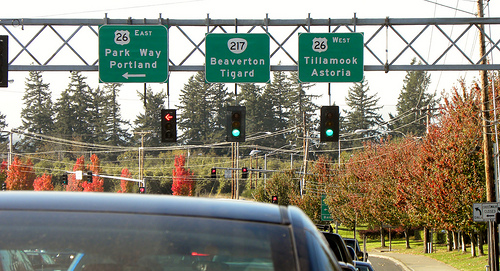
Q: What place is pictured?
A: It is a street.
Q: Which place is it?
A: It is a street.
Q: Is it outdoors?
A: Yes, it is outdoors.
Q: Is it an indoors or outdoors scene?
A: It is outdoors.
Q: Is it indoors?
A: No, it is outdoors.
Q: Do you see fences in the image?
A: No, there are no fences.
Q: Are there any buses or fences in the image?
A: No, there are no fences or buses.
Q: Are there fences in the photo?
A: No, there are no fences.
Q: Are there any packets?
A: No, there are no packets.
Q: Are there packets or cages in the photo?
A: No, there are no packets or cages.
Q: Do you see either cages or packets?
A: No, there are no packets or cages.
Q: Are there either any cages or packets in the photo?
A: No, there are no packets or cages.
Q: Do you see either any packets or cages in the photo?
A: No, there are no packets or cages.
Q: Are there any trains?
A: No, there are no trains.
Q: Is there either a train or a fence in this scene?
A: No, there are no trains or fences.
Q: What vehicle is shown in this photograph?
A: The vehicle is a car.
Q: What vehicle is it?
A: The vehicle is a car.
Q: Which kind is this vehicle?
A: This is a car.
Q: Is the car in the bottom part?
A: Yes, the car is in the bottom of the image.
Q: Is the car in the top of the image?
A: No, the car is in the bottom of the image.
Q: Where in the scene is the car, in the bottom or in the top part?
A: The car is in the bottom of the image.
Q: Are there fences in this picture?
A: No, there are no fences.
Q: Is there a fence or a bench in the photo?
A: No, there are no fences or benches.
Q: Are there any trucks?
A: No, there are no trucks.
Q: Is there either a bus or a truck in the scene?
A: No, there are no trucks or buses.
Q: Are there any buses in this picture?
A: No, there are no buses.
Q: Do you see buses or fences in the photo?
A: No, there are no buses or fences.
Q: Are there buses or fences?
A: No, there are no buses or fences.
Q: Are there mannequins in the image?
A: No, there are no mannequins.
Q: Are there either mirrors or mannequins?
A: No, there are no mannequins or mirrors.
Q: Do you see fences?
A: No, there are no fences.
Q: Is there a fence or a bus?
A: No, there are no fences or buses.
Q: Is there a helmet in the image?
A: No, there are no helmets.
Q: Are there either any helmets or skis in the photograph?
A: No, there are no helmets or skis.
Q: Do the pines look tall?
A: Yes, the pines are tall.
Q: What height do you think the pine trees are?
A: The pine trees are tall.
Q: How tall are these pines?
A: The pines are tall.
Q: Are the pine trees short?
A: No, the pine trees are tall.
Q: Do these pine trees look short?
A: No, the pine trees are tall.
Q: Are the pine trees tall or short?
A: The pine trees are tall.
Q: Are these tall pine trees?
A: Yes, these are tall pine trees.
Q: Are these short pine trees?
A: No, these are tall pine trees.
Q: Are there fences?
A: No, there are no fences.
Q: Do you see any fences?
A: No, there are no fences.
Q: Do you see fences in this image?
A: No, there are no fences.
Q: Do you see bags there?
A: No, there are no bags.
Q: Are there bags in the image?
A: No, there are no bags.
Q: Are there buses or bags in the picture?
A: No, there are no bags or buses.